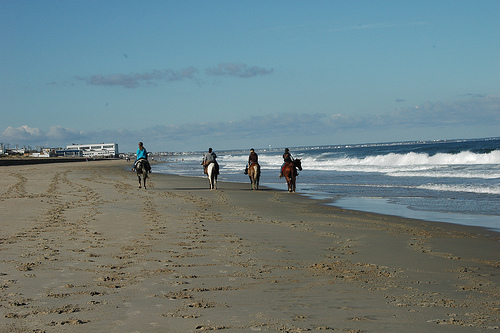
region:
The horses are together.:
[117, 123, 337, 203]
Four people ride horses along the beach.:
[115, 129, 331, 197]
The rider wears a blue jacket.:
[125, 135, 166, 166]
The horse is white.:
[192, 157, 228, 194]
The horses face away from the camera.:
[115, 132, 325, 200]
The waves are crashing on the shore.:
[310, 141, 496, 187]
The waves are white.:
[304, 145, 497, 184]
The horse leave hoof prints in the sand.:
[134, 190, 441, 324]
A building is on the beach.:
[12, 130, 123, 163]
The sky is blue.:
[0, 1, 497, 95]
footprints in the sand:
[155, 220, 217, 287]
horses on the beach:
[96, 136, 326, 199]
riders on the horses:
[106, 125, 313, 172]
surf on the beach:
[244, 142, 486, 214]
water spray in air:
[390, 148, 432, 163]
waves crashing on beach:
[396, 142, 470, 174]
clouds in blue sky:
[73, 52, 288, 101]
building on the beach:
[37, 125, 120, 187]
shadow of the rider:
[161, 177, 218, 196]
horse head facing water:
[289, 155, 306, 170]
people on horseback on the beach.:
[100, 101, 357, 236]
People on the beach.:
[103, 135, 428, 253]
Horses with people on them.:
[106, 124, 399, 236]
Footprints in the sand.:
[111, 186, 277, 301]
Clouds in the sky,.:
[94, 30, 359, 116]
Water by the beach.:
[263, 137, 392, 239]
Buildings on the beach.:
[62, 120, 130, 190]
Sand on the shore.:
[156, 197, 493, 284]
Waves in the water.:
[370, 141, 476, 198]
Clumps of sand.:
[282, 203, 409, 326]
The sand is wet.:
[6, 249, 266, 321]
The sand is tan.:
[1, 215, 206, 331]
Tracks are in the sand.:
[0, 217, 162, 329]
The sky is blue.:
[301, 17, 421, 68]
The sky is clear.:
[317, 33, 469, 86]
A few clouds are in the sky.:
[306, 74, 438, 131]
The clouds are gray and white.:
[311, 87, 403, 128]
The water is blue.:
[428, 141, 483, 159]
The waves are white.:
[387, 147, 497, 174]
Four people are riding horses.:
[116, 133, 341, 221]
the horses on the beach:
[117, 121, 311, 203]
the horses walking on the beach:
[125, 135, 302, 198]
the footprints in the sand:
[17, 187, 302, 331]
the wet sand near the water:
[329, 166, 434, 236]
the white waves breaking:
[315, 150, 498, 183]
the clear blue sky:
[311, 5, 495, 103]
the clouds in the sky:
[52, 57, 309, 142]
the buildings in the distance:
[6, 132, 123, 172]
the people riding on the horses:
[128, 135, 291, 169]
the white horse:
[198, 160, 223, 190]